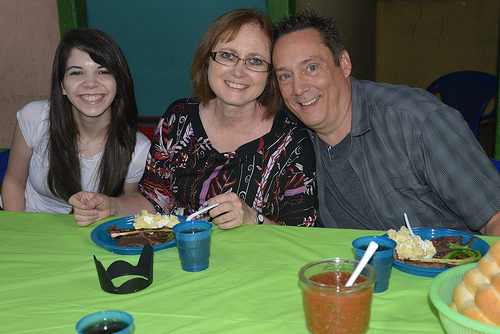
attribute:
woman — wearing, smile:
[1, 12, 174, 266]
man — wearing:
[257, 7, 467, 253]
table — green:
[1, 220, 88, 305]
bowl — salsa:
[309, 266, 378, 333]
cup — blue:
[177, 231, 212, 273]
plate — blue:
[82, 208, 152, 259]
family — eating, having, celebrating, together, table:
[22, 19, 449, 278]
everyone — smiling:
[43, 30, 378, 243]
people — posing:
[46, 21, 383, 190]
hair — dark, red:
[105, 129, 131, 176]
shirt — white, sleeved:
[32, 145, 87, 201]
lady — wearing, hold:
[23, 13, 159, 212]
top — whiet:
[18, 157, 56, 210]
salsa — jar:
[302, 301, 365, 331]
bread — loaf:
[457, 262, 491, 307]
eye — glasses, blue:
[218, 47, 274, 86]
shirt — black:
[149, 112, 202, 172]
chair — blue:
[434, 69, 481, 129]